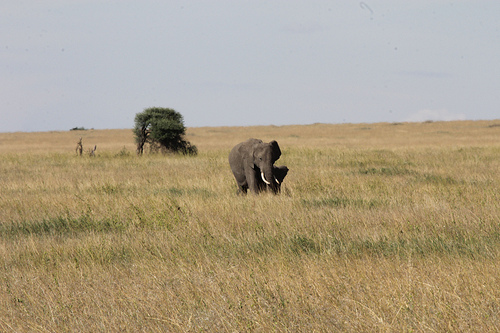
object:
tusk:
[273, 175, 279, 184]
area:
[3, 125, 498, 317]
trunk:
[75, 137, 83, 157]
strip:
[0, 220, 499, 266]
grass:
[254, 261, 500, 333]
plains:
[25, 136, 464, 273]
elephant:
[228, 138, 281, 197]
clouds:
[34, 30, 84, 59]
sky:
[9, 3, 78, 19]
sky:
[331, 104, 480, 118]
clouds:
[408, 26, 465, 66]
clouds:
[205, 9, 272, 29]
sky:
[270, 81, 399, 102]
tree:
[131, 106, 188, 155]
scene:
[8, 94, 457, 254]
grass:
[62, 269, 218, 318]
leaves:
[157, 121, 179, 132]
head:
[253, 143, 274, 173]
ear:
[269, 140, 281, 164]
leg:
[237, 176, 247, 197]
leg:
[245, 174, 259, 196]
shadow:
[273, 165, 289, 194]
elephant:
[273, 165, 289, 193]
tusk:
[260, 170, 270, 184]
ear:
[238, 138, 263, 169]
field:
[70, 208, 465, 308]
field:
[20, 132, 231, 234]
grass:
[69, 159, 118, 176]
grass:
[0, 210, 73, 242]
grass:
[401, 230, 495, 258]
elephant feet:
[236, 188, 277, 195]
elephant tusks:
[273, 175, 280, 185]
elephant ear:
[277, 165, 288, 183]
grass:
[351, 117, 500, 172]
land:
[1, 119, 499, 333]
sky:
[16, 95, 78, 118]